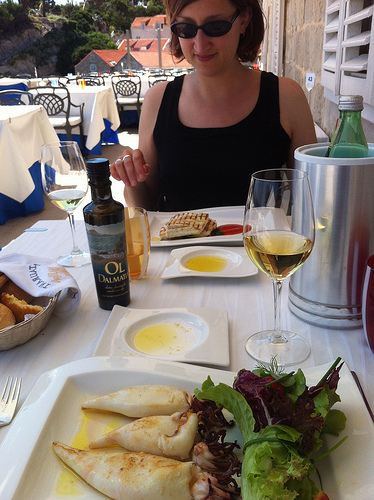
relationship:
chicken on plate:
[80, 384, 195, 417] [1, 355, 374, 499]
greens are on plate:
[187, 354, 349, 499] [1, 355, 374, 499]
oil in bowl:
[136, 324, 177, 353] [92, 302, 230, 366]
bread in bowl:
[1, 274, 41, 326] [0, 286, 61, 352]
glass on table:
[243, 168, 316, 366] [2, 219, 373, 444]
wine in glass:
[244, 230, 313, 284] [243, 168, 316, 366]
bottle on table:
[80, 158, 131, 311] [2, 219, 373, 444]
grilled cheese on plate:
[160, 210, 219, 239] [145, 204, 248, 249]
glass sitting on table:
[243, 168, 316, 366] [2, 219, 373, 444]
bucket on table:
[286, 140, 374, 331] [2, 219, 373, 444]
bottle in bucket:
[326, 95, 370, 157] [286, 140, 374, 331]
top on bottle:
[338, 96, 364, 114] [326, 95, 370, 157]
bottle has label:
[80, 158, 131, 311] [80, 218, 131, 299]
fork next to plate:
[0, 376, 21, 426] [1, 355, 374, 499]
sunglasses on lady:
[169, 5, 242, 37] [109, 1, 320, 213]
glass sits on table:
[243, 168, 316, 366] [2, 219, 373, 444]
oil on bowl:
[136, 324, 177, 353] [92, 302, 230, 366]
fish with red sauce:
[160, 210, 217, 239] [219, 222, 251, 235]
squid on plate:
[53, 383, 241, 500] [1, 355, 374, 499]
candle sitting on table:
[78, 79, 88, 89] [18, 88, 121, 154]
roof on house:
[74, 13, 191, 64] [74, 13, 193, 73]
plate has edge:
[145, 204, 248, 249] [150, 232, 245, 253]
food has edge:
[158, 211, 216, 240] [158, 223, 212, 237]